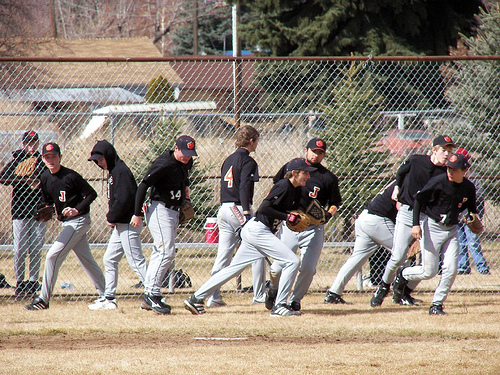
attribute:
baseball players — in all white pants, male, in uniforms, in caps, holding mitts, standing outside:
[7, 130, 495, 306]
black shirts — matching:
[406, 161, 458, 202]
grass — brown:
[76, 351, 139, 364]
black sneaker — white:
[154, 134, 208, 317]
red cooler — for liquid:
[203, 216, 223, 248]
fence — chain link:
[302, 80, 348, 88]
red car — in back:
[373, 118, 426, 156]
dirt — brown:
[90, 332, 147, 352]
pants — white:
[148, 198, 193, 298]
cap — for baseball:
[451, 154, 458, 169]